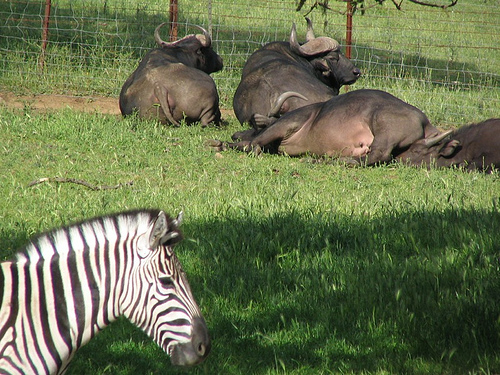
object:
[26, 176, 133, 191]
branch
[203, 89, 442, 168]
animal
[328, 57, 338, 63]
eye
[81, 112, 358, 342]
photo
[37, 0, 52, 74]
post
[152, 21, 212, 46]
horns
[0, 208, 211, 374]
animal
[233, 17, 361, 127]
animal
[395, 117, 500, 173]
animal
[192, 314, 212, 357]
nose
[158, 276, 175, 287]
eye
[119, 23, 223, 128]
animal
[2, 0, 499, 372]
greengrass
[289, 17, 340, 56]
horn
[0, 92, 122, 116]
brown dirt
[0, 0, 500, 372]
grass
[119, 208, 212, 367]
head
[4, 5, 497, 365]
ground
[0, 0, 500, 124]
fence